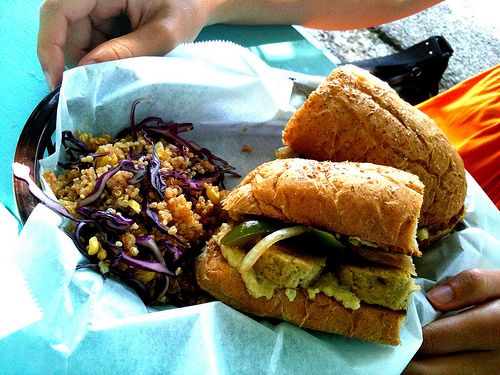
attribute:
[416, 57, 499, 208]
shirt — orange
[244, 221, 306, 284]
onion — thin, sliced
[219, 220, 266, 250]
slice — shiny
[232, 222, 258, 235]
skin — sliced, green, pepper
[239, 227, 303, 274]
onion — white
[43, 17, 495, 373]
bench — gray, wooden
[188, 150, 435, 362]
sandwich — large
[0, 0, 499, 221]
table — light green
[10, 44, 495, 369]
basket — black, plastic